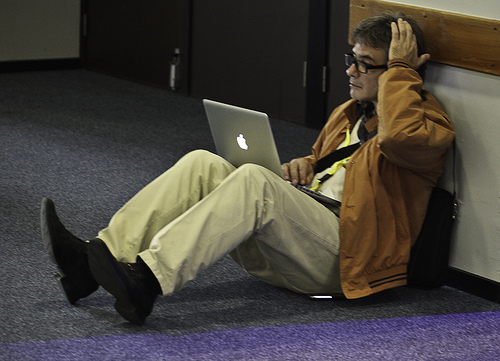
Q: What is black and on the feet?
A: Shoes.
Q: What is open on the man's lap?
A: A laptop computer.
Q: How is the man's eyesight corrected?
A: Eyeglasses.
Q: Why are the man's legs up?
A: Hold up the laptop.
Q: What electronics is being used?
A: Laptop.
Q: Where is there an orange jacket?
A: On the man's body.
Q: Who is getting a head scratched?
A: Man with laptop.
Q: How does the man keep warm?
A: Jacket.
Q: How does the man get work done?
A: Using the laptop.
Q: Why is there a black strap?
A: Hold up bag.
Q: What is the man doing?
A: Sitting on the floor and using a laptop.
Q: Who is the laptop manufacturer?
A: Apple.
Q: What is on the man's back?
A: A bag.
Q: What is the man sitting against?
A: A wall.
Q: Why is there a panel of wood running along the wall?
A: It is there to decorate the wall.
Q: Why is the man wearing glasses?
A: So he can see properly.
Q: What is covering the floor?
A: Carpet.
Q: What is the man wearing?
A: Khakis, a yellow shirt, an orange jacket, and black shoes.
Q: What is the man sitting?
A: On carpet.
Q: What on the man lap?
A: A laptop.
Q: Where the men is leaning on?
A: A wall.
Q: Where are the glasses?
A: On his face.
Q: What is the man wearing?
A: Black shoe.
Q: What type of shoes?
A: Loafers.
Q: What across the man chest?
A: Strap.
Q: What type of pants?
A: Khaki.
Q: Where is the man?
A: On the ground.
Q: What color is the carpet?
A: Blue.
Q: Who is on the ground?
A: The man.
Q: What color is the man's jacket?
A: Orange.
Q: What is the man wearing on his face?
A: Glasses.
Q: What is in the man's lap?
A: A computer.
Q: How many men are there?
A: One.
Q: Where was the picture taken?
A: At an airport.